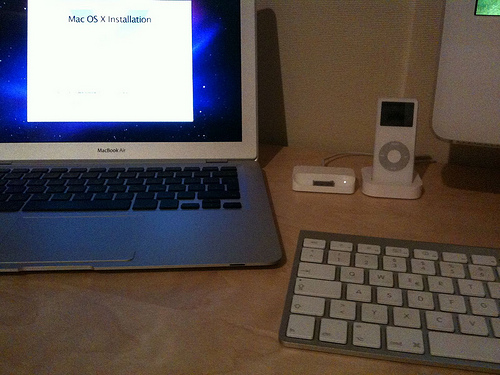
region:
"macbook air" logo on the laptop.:
[93, 144, 138, 156]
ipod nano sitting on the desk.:
[371, 97, 418, 190]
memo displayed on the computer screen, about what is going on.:
[63, 9, 157, 31]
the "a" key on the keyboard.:
[346, 282, 369, 307]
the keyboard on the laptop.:
[7, 165, 249, 214]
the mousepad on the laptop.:
[11, 218, 146, 265]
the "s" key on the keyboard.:
[375, 285, 405, 310]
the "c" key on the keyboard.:
[425, 313, 456, 331]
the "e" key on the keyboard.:
[429, 276, 451, 295]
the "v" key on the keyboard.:
[461, 315, 489, 337]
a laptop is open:
[3, 0, 290, 282]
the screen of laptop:
[0, 3, 265, 162]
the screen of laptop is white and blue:
[3, 3, 253, 153]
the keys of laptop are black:
[2, 151, 249, 221]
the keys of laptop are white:
[278, 222, 498, 363]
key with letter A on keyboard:
[342, 278, 372, 301]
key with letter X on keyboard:
[388, 302, 423, 328]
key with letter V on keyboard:
[459, 311, 489, 336]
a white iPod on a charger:
[356, 88, 427, 200]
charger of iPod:
[356, 157, 427, 202]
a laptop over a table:
[2, 0, 292, 277]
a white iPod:
[371, 86, 422, 187]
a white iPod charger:
[356, 163, 425, 200]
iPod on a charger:
[359, 88, 427, 205]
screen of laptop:
[0, 3, 262, 163]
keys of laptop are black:
[6, 163, 247, 222]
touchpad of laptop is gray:
[2, 200, 142, 268]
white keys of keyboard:
[280, 222, 497, 367]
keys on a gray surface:
[265, 218, 496, 363]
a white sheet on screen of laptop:
[2, 3, 259, 157]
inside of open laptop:
[3, 2, 284, 276]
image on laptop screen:
[5, 1, 243, 143]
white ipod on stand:
[360, 97, 422, 197]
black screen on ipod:
[380, 99, 415, 126]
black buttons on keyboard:
[0, 163, 242, 210]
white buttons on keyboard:
[277, 227, 499, 371]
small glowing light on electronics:
[291, 164, 353, 194]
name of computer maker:
[95, 145, 126, 153]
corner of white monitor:
[428, 2, 495, 147]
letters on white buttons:
[346, 268, 480, 312]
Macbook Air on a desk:
[5, 1, 290, 287]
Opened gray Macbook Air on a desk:
[4, 2, 289, 279]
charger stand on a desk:
[284, 76, 359, 205]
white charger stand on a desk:
[285, 136, 357, 201]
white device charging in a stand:
[362, 88, 431, 208]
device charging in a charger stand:
[359, 78, 424, 210]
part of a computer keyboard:
[277, 201, 499, 372]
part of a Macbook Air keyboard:
[5, 161, 270, 216]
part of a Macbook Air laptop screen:
[10, 0, 274, 159]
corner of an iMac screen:
[431, 0, 499, 187]